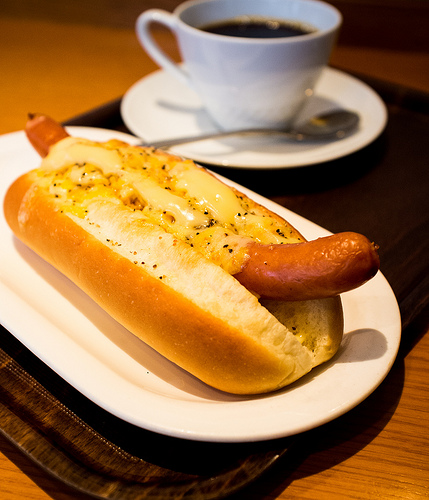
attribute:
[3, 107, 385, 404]
hot dog — ready, well done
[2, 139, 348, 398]
roll — toasted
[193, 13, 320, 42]
coffee — black, hot, dark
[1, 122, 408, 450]
plate — white, long, oval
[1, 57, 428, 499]
place mat — brown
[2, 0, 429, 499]
table — wooden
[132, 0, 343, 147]
cup — white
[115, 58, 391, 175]
saucer — white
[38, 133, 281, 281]
cheese — yellow